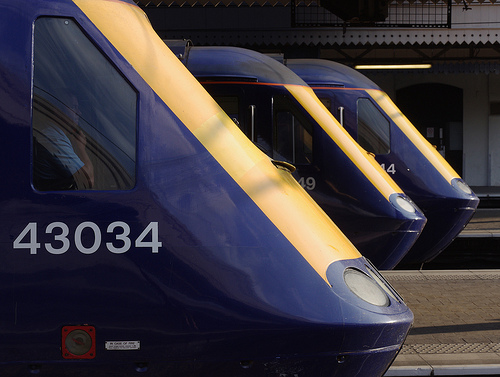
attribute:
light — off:
[354, 58, 436, 73]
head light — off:
[340, 264, 393, 310]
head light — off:
[390, 192, 417, 214]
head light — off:
[454, 177, 474, 196]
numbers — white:
[298, 174, 315, 189]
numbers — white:
[378, 162, 394, 174]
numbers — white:
[12, 218, 166, 255]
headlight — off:
[327, 253, 415, 325]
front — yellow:
[217, 50, 432, 263]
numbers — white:
[17, 205, 190, 282]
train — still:
[92, 40, 333, 340]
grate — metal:
[292, 4, 487, 44]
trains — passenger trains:
[203, 47, 458, 244]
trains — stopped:
[4, 92, 381, 374]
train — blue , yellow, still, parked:
[1, 1, 413, 376]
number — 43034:
[23, 214, 163, 258]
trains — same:
[22, 22, 470, 368]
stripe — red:
[310, 87, 367, 92]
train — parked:
[189, 29, 434, 283]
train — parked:
[296, 41, 498, 264]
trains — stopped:
[9, 3, 480, 375]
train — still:
[158, 37, 428, 267]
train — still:
[264, 51, 480, 269]